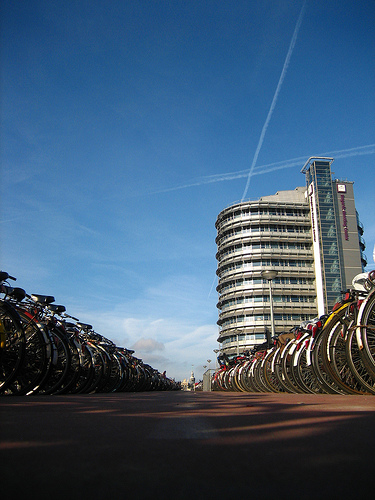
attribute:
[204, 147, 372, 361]
building — shiny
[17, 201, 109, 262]
clouds — white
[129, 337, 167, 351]
cloud — white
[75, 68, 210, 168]
sky — blue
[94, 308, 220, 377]
clouds — white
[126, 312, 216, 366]
clouds — white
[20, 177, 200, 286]
clouds — white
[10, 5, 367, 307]
sky — blue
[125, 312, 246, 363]
cloud — white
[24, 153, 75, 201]
clouds — white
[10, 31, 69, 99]
sky — blue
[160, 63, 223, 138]
sky — blue, white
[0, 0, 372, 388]
sky — blue, clear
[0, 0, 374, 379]
clouds — white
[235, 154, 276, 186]
clouds — white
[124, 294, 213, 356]
clouds — white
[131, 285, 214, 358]
clouds — white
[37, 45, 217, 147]
sky — blue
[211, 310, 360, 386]
bicycles — row, long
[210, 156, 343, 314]
tower — tall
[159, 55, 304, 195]
jet — contrail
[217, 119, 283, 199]
jet — contrail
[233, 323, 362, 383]
bike — tire